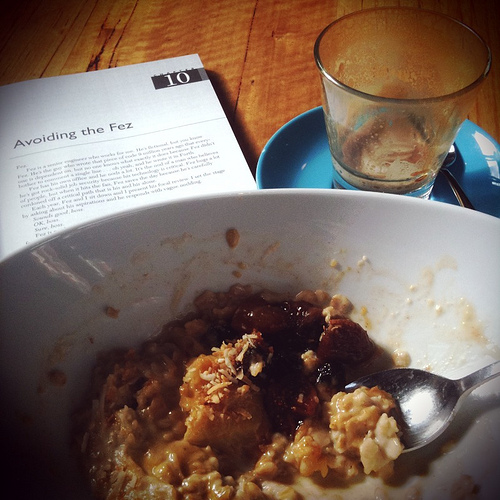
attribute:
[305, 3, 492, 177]
glass — empty, small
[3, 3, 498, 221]
table — light, wooden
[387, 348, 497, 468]
spoon — metal, silver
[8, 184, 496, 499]
bowl — white, round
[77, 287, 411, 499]
porridge — black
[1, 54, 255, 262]
paper — white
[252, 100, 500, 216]
plate — blue, small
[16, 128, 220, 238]
text — black